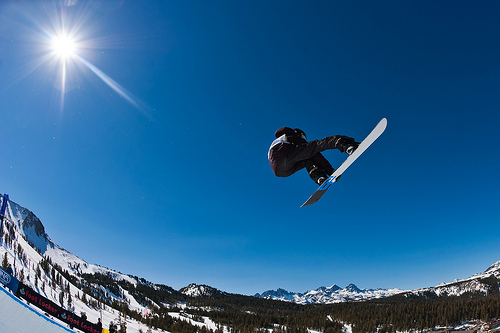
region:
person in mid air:
[256, 120, 391, 214]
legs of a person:
[278, 131, 360, 186]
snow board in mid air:
[298, 93, 399, 225]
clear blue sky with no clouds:
[121, 153, 235, 208]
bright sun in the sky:
[31, 17, 92, 77]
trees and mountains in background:
[190, 264, 499, 321]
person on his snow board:
[245, 73, 385, 207]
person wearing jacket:
[239, 95, 413, 202]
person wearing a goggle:
[249, 71, 407, 225]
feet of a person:
[337, 135, 362, 154]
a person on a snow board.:
[263, 103, 398, 217]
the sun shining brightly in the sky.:
[12, 0, 160, 131]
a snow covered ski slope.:
[1, 196, 181, 328]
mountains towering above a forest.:
[253, 268, 418, 308]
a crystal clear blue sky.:
[0, 0, 498, 297]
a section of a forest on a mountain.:
[218, 300, 263, 322]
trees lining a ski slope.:
[0, 257, 95, 317]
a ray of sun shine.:
[72, 62, 172, 123]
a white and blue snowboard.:
[300, 110, 397, 211]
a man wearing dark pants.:
[272, 131, 337, 188]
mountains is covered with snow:
[238, 263, 388, 304]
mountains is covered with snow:
[256, 265, 399, 330]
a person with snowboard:
[210, 89, 401, 251]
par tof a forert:
[358, 293, 373, 318]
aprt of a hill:
[178, 257, 211, 311]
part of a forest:
[356, 293, 381, 332]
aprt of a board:
[301, 170, 331, 247]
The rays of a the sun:
[36, 22, 103, 82]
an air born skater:
[273, 108, 383, 201]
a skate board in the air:
[357, 118, 402, 178]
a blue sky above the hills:
[181, 32, 453, 111]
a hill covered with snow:
[3, 201, 59, 275]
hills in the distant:
[271, 273, 370, 302]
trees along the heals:
[223, 297, 424, 328]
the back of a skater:
[270, 128, 293, 160]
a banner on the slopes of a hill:
[11, 283, 80, 319]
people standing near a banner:
[68, 309, 108, 325]